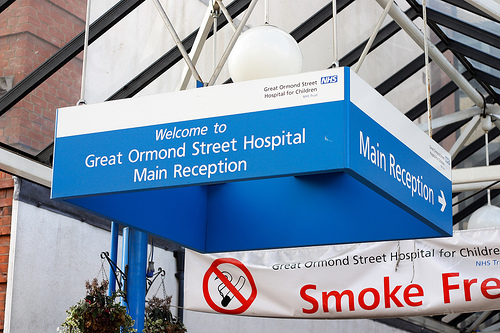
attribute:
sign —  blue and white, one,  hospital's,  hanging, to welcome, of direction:
[49, 59, 456, 255]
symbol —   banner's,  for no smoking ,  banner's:
[202, 257, 256, 313]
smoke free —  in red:
[300, 271, 498, 314]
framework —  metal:
[155, 2, 225, 83]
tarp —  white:
[11, 202, 181, 316]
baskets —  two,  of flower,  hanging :
[60, 279, 185, 331]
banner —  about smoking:
[182, 231, 498, 314]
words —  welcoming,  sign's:
[82, 119, 309, 182]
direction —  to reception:
[353, 130, 451, 211]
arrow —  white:
[433, 184, 449, 214]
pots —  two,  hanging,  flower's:
[58, 280, 187, 330]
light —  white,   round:
[226, 24, 307, 84]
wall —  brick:
[178, 248, 494, 331]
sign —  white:
[178, 202, 498, 320]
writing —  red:
[297, 277, 426, 311]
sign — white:
[165, 246, 492, 319]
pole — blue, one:
[120, 227, 150, 330]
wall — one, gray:
[25, 226, 66, 301]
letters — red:
[299, 271, 492, 313]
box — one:
[28, 57, 454, 251]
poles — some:
[54, 3, 458, 129]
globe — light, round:
[192, 11, 309, 84]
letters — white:
[347, 110, 456, 235]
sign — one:
[47, 80, 455, 257]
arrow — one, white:
[436, 186, 446, 216]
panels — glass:
[95, 6, 488, 96]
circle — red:
[199, 252, 254, 316]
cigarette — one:
[210, 268, 245, 311]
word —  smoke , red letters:
[296, 270, 424, 314]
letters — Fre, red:
[432, 261, 482, 331]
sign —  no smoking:
[196, 248, 479, 324]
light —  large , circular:
[233, 22, 308, 81]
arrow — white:
[434, 183, 454, 203]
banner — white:
[186, 244, 483, 331]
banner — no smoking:
[179, 239, 483, 324]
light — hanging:
[228, 19, 299, 88]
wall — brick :
[8, 3, 56, 119]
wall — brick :
[4, 12, 47, 167]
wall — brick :
[4, 2, 64, 162]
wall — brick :
[3, 1, 73, 187]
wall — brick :
[7, 1, 55, 154]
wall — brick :
[4, 3, 74, 145]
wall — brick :
[4, 3, 68, 155]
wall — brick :
[1, 4, 81, 181]